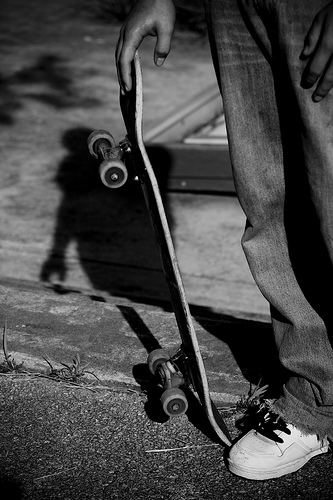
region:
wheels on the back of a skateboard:
[146, 340, 189, 416]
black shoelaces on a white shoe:
[253, 415, 286, 441]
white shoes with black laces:
[225, 408, 325, 476]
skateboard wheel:
[161, 384, 184, 411]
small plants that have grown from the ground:
[0, 319, 99, 385]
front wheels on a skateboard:
[89, 127, 129, 187]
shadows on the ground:
[37, 116, 282, 385]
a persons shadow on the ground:
[37, 112, 178, 307]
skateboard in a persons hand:
[85, 0, 233, 452]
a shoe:
[226, 406, 332, 481]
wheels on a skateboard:
[87, 130, 126, 188]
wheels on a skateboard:
[148, 348, 187, 416]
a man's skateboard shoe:
[228, 409, 331, 481]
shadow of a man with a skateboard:
[46, 126, 289, 399]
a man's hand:
[116, 2, 175, 92]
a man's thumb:
[155, 33, 168, 67]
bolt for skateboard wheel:
[172, 403, 178, 412]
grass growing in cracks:
[0, 319, 96, 392]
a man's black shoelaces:
[252, 413, 289, 442]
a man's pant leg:
[201, 3, 331, 437]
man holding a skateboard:
[84, 0, 307, 495]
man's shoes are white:
[215, 371, 317, 495]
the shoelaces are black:
[248, 410, 292, 448]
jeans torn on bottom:
[279, 389, 326, 445]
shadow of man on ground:
[39, 108, 171, 338]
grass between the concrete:
[2, 341, 106, 398]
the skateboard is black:
[196, 380, 236, 457]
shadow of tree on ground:
[8, 36, 123, 160]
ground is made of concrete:
[2, 8, 295, 454]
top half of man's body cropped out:
[2, 0, 327, 225]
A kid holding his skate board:
[83, 2, 332, 498]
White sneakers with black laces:
[219, 391, 331, 490]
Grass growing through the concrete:
[0, 314, 106, 395]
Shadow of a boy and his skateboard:
[34, 113, 291, 421]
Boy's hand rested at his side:
[288, 2, 332, 107]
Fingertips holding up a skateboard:
[97, 2, 186, 114]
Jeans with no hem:
[199, 0, 332, 453]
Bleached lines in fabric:
[197, 1, 331, 81]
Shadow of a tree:
[0, 48, 108, 136]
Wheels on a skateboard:
[134, 344, 193, 421]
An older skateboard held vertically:
[85, 45, 234, 447]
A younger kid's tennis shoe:
[224, 405, 331, 482]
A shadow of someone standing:
[34, 125, 183, 311]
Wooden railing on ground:
[141, 80, 242, 197]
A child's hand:
[112, 2, 178, 95]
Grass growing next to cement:
[42, 349, 92, 383]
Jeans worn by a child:
[202, 0, 332, 428]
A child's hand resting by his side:
[297, 6, 330, 106]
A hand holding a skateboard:
[86, 2, 237, 449]